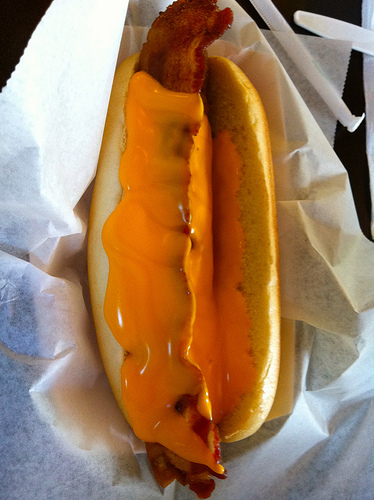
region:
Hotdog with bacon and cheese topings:
[80, 0, 275, 495]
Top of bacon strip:
[118, 2, 261, 92]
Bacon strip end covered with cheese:
[106, 368, 261, 492]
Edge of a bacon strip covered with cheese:
[145, 9, 234, 483]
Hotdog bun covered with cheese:
[219, 53, 280, 414]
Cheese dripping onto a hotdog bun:
[104, 77, 164, 402]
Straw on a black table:
[246, 1, 340, 138]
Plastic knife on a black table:
[284, 2, 372, 109]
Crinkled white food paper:
[271, 29, 366, 479]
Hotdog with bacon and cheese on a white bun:
[13, 1, 339, 492]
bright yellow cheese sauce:
[94, 69, 255, 478]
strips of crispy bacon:
[141, 1, 235, 498]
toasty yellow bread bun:
[80, 48, 289, 446]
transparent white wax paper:
[1, 0, 371, 499]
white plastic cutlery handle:
[289, 4, 372, 56]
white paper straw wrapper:
[247, 0, 365, 135]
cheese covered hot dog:
[191, 109, 227, 409]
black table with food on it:
[234, 0, 371, 254]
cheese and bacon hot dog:
[87, 3, 288, 497]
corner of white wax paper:
[301, 34, 361, 72]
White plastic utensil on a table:
[295, 9, 373, 53]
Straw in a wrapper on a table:
[249, 0, 366, 144]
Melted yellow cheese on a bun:
[117, 77, 243, 438]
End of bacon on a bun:
[140, 0, 224, 94]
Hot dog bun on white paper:
[83, 48, 287, 446]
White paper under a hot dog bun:
[2, 0, 371, 499]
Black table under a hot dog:
[0, 0, 373, 245]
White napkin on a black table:
[358, 0, 372, 241]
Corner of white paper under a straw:
[258, 26, 349, 149]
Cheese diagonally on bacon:
[152, 410, 226, 476]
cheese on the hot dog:
[99, 71, 260, 448]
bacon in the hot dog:
[144, 0, 243, 95]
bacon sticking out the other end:
[132, 392, 221, 488]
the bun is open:
[76, 46, 287, 436]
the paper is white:
[3, 2, 371, 497]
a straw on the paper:
[263, 0, 364, 139]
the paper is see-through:
[1, 240, 358, 498]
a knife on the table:
[288, 3, 371, 61]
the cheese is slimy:
[83, 76, 250, 429]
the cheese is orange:
[96, 51, 284, 493]